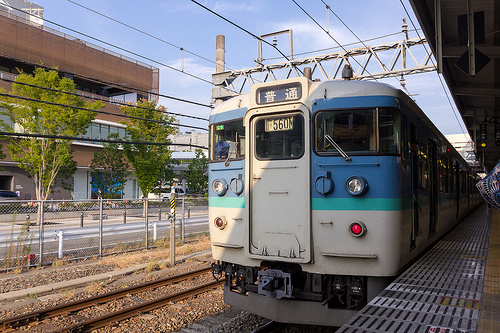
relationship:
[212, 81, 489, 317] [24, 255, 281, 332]
train on tracks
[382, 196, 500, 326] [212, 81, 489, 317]
platform next to train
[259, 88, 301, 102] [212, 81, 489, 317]
sign on train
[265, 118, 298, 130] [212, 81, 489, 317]
number on train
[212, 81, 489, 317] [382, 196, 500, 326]
train next to platform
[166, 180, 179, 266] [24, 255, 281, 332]
post next to tracks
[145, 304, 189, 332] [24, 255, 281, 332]
rocks on tracks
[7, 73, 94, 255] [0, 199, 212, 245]
tree behind fence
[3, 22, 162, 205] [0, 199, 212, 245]
building behind fence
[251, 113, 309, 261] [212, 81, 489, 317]
door on train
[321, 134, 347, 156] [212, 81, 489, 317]
windshield wiper on train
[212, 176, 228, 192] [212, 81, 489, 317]
lights on train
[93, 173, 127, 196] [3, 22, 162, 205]
window on building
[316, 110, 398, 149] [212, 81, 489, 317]
windshield on train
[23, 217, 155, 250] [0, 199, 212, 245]
sidewalk next to fence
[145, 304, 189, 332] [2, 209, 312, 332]
rocks on ground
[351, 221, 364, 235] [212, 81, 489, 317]
light on train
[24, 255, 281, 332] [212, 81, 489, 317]
tracks under train